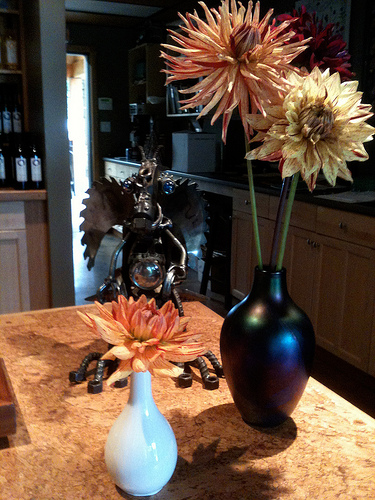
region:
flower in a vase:
[81, 307, 179, 490]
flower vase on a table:
[98, 367, 188, 497]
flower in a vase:
[270, 68, 367, 195]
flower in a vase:
[180, 12, 282, 177]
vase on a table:
[225, 235, 322, 445]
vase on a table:
[97, 372, 177, 490]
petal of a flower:
[150, 357, 181, 375]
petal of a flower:
[112, 360, 134, 385]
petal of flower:
[144, 316, 167, 336]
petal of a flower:
[85, 311, 118, 336]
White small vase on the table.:
[70, 352, 205, 491]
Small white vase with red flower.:
[68, 292, 203, 491]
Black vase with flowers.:
[157, 0, 367, 425]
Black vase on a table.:
[213, 260, 313, 426]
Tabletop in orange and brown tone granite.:
[2, 292, 367, 490]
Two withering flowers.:
[157, 1, 367, 184]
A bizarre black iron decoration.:
[65, 145, 221, 388]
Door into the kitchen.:
[60, 45, 99, 240]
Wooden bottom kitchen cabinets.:
[222, 176, 369, 373]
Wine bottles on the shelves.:
[0, 27, 41, 188]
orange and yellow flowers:
[147, 31, 341, 193]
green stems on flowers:
[228, 170, 313, 271]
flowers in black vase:
[225, 270, 315, 452]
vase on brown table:
[228, 261, 305, 446]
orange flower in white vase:
[92, 303, 210, 483]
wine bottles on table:
[12, 137, 45, 188]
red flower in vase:
[264, 7, 344, 104]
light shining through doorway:
[65, 52, 107, 302]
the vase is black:
[216, 253, 321, 442]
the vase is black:
[214, 256, 316, 449]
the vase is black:
[211, 245, 316, 459]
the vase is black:
[235, 254, 305, 439]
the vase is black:
[220, 263, 327, 453]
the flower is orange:
[93, 294, 187, 395]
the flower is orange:
[83, 289, 205, 401]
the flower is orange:
[75, 286, 198, 388]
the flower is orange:
[85, 295, 193, 383]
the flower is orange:
[88, 287, 184, 389]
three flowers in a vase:
[181, 7, 370, 426]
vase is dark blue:
[231, 270, 311, 420]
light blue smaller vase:
[109, 373, 174, 496]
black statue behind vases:
[82, 143, 196, 300]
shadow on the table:
[188, 459, 263, 499]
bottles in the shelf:
[0, 118, 64, 181]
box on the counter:
[169, 129, 222, 182]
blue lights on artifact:
[115, 176, 186, 210]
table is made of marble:
[307, 398, 372, 499]